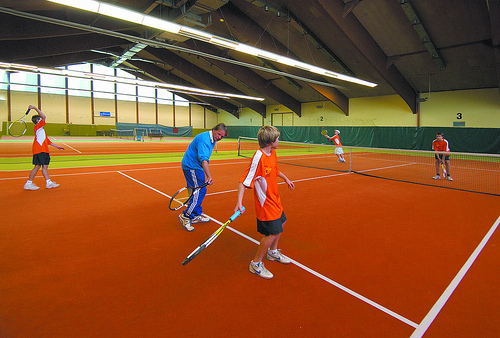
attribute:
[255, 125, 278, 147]
hair — BLONDE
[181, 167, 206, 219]
pants — BLUE 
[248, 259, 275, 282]
shoes — white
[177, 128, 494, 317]
court — orange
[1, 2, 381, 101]
lights — LONG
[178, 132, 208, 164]
shirt — BLUE 